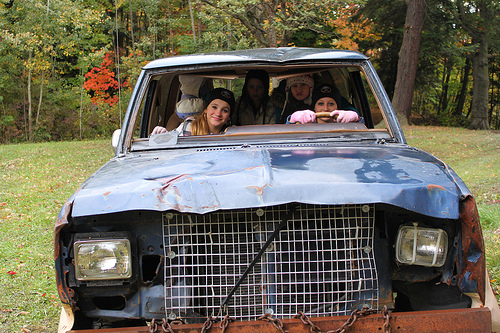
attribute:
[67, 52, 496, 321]
car — blue, old, steering, beautiful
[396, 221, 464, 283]
headlight — old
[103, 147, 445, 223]
hood — bent, beatup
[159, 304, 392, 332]
chain — iron, small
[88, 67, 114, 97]
leaves — red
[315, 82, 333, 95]
cap — black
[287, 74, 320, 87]
cap — white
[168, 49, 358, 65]
roof — dented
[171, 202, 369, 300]
grill — metal, exposed, uncovered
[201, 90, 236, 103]
hat — black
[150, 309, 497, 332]
bumper — rusted, rusty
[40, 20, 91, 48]
leaves — green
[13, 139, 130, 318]
field — grassy, green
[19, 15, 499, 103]
trees — large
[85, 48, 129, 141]
tree — red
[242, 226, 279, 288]
thread — black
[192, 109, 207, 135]
hair — brown